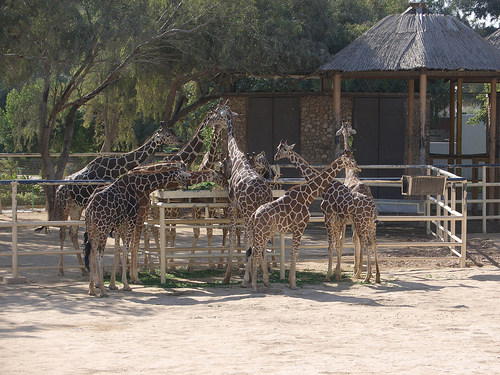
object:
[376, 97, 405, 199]
door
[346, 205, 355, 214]
spots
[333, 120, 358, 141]
giraffe head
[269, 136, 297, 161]
giraffe head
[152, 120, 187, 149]
giraffe head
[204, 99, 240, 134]
giraffe head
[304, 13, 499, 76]
roof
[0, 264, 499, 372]
sand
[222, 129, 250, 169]
neck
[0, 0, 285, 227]
tree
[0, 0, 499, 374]
zoo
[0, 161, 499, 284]
fence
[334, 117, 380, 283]
giraffe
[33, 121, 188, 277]
giraffe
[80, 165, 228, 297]
giraffe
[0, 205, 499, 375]
floor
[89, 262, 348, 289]
plants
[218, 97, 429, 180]
rock wall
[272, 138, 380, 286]
giraffe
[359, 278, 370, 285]
feet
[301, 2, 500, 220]
house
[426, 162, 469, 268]
iron fence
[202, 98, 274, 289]
giraffe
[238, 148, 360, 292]
giraffe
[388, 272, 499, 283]
shadows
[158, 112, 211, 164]
mane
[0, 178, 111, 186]
paint